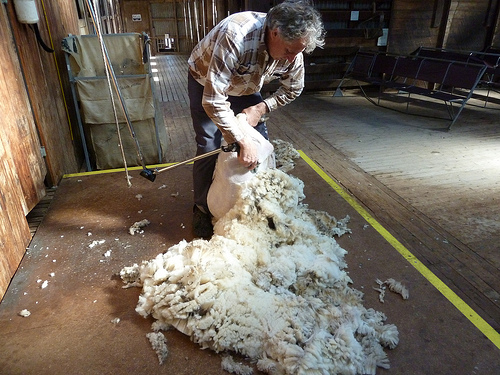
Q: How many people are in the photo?
A: One.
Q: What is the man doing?
A: Shearing a sheep.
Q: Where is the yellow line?
A: Floor.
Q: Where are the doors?
A: Left side of the man.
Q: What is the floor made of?
A: Wood.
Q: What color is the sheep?
A: White.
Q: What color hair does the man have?
A: Gray.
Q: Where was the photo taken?
A: In a barn.